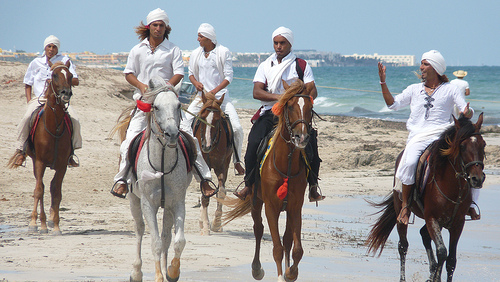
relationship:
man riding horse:
[14, 35, 82, 167] [24, 58, 75, 233]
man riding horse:
[109, 7, 219, 197] [118, 90, 194, 280]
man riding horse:
[182, 19, 249, 175] [193, 88, 233, 230]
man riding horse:
[233, 26, 325, 202] [246, 83, 315, 281]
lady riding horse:
[378, 50, 475, 225] [388, 115, 485, 280]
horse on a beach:
[24, 58, 75, 233] [0, 57, 492, 276]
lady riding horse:
[378, 50, 475, 225] [363, 109, 490, 280]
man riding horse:
[233, 27, 328, 207] [203, 80, 318, 280]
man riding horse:
[109, 7, 219, 197] [113, 70, 198, 280]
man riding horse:
[4, 30, 84, 171] [10, 57, 75, 237]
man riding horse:
[182, 19, 249, 175] [182, 88, 240, 229]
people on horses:
[51, 24, 488, 144] [29, 103, 480, 259]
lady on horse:
[378, 50, 475, 225] [385, 130, 480, 231]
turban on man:
[278, 19, 311, 54] [233, 26, 325, 202]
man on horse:
[109, 7, 219, 197] [126, 90, 221, 280]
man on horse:
[111, 13, 207, 116] [127, 85, 199, 215]